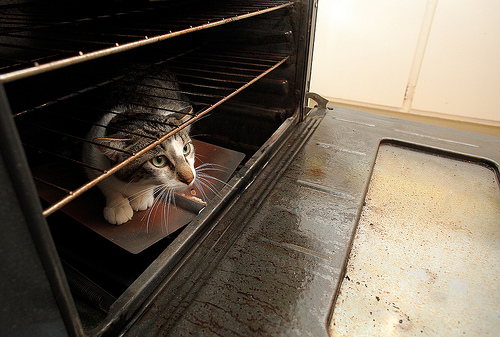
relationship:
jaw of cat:
[149, 170, 180, 198] [75, 98, 270, 270]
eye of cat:
[149, 149, 170, 171] [76, 80, 296, 274]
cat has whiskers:
[84, 68, 207, 230] [136, 162, 240, 242]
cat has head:
[84, 68, 207, 230] [94, 105, 201, 193]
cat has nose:
[84, 68, 207, 230] [177, 164, 194, 190]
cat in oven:
[84, 68, 207, 230] [4, 2, 326, 331]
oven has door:
[4, 2, 326, 331] [128, 76, 498, 335]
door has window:
[128, 76, 498, 335] [334, 132, 499, 336]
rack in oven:
[0, 4, 296, 218] [4, 2, 326, 331]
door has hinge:
[128, 76, 498, 335] [302, 84, 328, 111]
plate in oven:
[33, 105, 245, 259] [4, 2, 326, 331]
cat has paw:
[84, 68, 207, 230] [105, 195, 134, 226]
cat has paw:
[84, 68, 207, 230] [129, 184, 159, 212]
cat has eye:
[84, 68, 207, 230] [149, 149, 170, 171]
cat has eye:
[84, 68, 207, 230] [183, 138, 194, 160]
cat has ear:
[84, 68, 207, 230] [95, 133, 129, 163]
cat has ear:
[84, 68, 207, 230] [172, 105, 195, 124]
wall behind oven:
[298, 0, 496, 128] [4, 2, 326, 331]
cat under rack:
[84, 68, 207, 230] [0, 4, 296, 218]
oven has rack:
[4, 2, 326, 331] [0, 4, 296, 218]